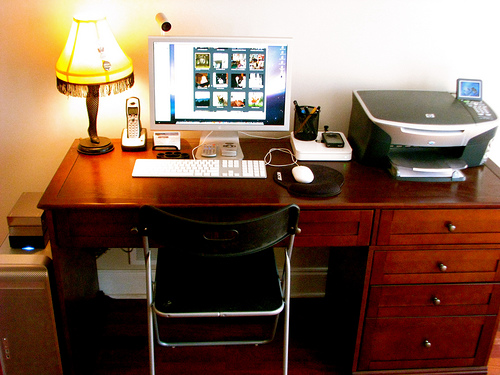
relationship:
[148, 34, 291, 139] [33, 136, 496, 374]
monitor sitting on desk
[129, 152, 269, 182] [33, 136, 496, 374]
keyboard sitting on desk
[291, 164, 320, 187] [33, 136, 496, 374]
mouse sitting on desk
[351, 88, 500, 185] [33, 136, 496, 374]
printer sitting on desk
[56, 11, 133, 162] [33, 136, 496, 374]
lamp sitting on desk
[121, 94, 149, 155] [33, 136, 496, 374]
phone sitting on desk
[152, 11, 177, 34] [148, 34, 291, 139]
camera above monitor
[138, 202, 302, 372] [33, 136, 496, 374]
chair sitting at desk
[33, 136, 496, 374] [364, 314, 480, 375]
desk has a drawer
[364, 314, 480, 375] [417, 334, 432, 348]
drawer has a knob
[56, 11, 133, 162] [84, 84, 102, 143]
lamp shaped like a leg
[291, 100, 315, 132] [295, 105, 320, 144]
pen in pencil holder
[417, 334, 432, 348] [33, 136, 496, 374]
knob on desk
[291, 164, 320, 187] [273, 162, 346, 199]
mouse sitting on mouse pad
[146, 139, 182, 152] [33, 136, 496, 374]
card holder sitting on desk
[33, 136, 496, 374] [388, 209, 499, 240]
desk has a drawer